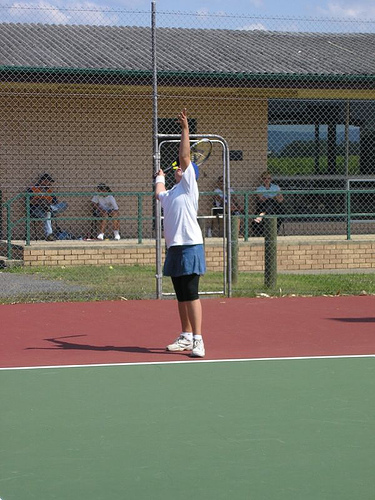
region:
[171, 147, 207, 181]
head of a person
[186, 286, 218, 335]
leg of a person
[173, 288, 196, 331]
leg of a person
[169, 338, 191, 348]
feet of a person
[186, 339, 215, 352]
feet of a person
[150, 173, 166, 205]
arm of a person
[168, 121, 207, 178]
arm of a person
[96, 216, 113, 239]
leg of a person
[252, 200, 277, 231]
leg of a person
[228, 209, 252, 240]
leg of a person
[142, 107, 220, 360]
Tennis player serving ball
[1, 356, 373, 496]
Green, smooth tennis court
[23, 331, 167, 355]
Shadow of a tennis player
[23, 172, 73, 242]
Man wearing a black baseball hat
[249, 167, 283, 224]
Woman watching tennis match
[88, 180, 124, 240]
Child wearing a ponytail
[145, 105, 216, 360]
Woman in a white t-shirt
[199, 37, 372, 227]
Large building next to tennis court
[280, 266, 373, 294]
Grass next to the tennis court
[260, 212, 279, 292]
Olive green pole next to fence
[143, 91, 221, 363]
the tennis oplayer waits for the ball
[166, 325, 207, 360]
the white pair of tennis shoe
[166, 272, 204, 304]
the black pants under the skirt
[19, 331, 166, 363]
the shadow on the court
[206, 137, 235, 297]
the gate for the chainlink fence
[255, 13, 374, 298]
the chainlink fence for the tennis court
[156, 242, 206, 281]
the skirt on the women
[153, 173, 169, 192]
the sweatband on the womens wrist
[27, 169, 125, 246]
the people sitting in the chairs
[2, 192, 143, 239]
the green handrail on the deck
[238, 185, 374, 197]
a long green pole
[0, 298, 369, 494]
part of a tennis court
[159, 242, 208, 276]
a woman's blue skirt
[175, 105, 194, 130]
the hand of a woman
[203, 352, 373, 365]
a long white line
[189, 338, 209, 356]
a woman's white tennis shoe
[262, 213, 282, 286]
a tall green pole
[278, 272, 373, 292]
a section of green grass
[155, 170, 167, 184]
a white wristband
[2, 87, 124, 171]
part of a brick building